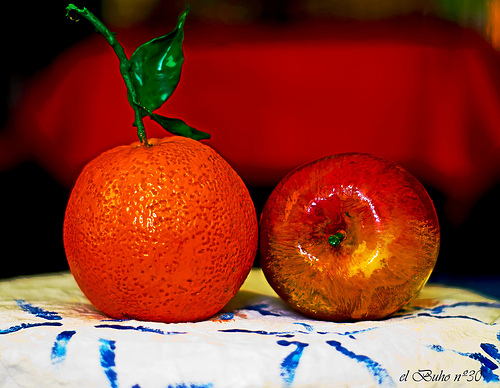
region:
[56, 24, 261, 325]
this is a orange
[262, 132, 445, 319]
this is an apple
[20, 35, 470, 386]
orange and apple on fabric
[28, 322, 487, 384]
blue designs on the fabric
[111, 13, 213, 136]
green leaf on orange stem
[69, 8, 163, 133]
this is a orange stem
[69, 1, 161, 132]
orange stem is green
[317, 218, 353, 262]
green stem on apple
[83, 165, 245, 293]
dimples on orange peel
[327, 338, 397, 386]
blue line on cloth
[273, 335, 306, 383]
blue line on cloth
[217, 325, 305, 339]
blue line on cloth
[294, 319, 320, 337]
blue line on cloth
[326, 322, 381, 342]
blue line on cloth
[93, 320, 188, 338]
blue line on cloth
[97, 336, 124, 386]
blue line on cloth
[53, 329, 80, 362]
blue line on cloth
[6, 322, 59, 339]
blue line on cloth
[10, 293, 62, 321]
blue line on cloth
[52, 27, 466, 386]
a couple of fruits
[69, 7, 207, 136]
the stem of an orange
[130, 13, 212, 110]
the left leaf on a stem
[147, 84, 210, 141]
the small leaf on a stem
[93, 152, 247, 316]
a medium sized orange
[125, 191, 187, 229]
the pores on an orange peel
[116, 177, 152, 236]
the light reflecting on a peel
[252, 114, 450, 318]
a small red apple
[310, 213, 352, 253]
the stem of an apple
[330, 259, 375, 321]
the rotting part of an apple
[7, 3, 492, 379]
the picture of fruits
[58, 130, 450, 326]
an orange and an apple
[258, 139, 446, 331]
apple is color yellow is red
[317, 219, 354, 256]
the stem of an apple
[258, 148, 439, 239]
part red of apple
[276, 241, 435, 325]
part yellow of apple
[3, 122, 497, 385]
fruits on a table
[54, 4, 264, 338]
stem on top an orange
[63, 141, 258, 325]
Th ecircle is orange.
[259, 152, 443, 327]
The circle is red and yellow.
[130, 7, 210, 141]
The leaves are green.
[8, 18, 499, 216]
Red is in the background.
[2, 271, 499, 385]
The surface is blue and white.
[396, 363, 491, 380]
A logo is on white.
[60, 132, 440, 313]
Two different pieces of fruit are on a surface.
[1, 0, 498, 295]
The background is blurry.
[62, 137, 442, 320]
An apple and an orange are next to each other.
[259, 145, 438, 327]
red apple next to the orange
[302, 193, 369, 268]
Top of a apple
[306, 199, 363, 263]
Top of a apple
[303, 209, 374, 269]
Top of a apple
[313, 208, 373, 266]
Top of a apple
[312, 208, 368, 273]
Top of a apple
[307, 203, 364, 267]
Top of a apple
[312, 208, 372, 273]
Top of a apple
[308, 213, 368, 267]
Top of a apple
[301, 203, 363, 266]
Top of a apple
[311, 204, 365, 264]
Top of a apple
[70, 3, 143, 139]
the stem is green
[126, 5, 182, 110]
the leaf is dark green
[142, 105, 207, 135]
the leaf is dark green